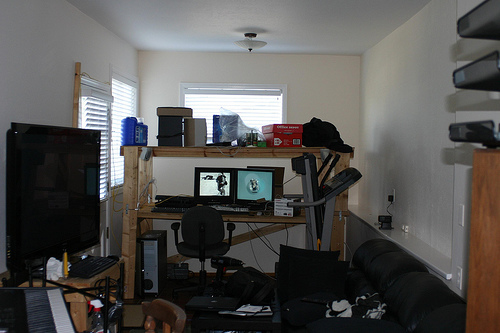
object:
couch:
[272, 236, 466, 332]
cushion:
[416, 303, 470, 333]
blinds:
[81, 96, 109, 200]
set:
[85, 87, 108, 195]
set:
[109, 82, 136, 187]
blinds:
[111, 77, 137, 188]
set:
[187, 95, 279, 139]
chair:
[169, 206, 237, 299]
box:
[261, 123, 304, 148]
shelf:
[119, 145, 352, 157]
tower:
[135, 229, 170, 300]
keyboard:
[69, 256, 117, 279]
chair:
[134, 297, 188, 333]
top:
[138, 297, 190, 333]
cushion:
[368, 251, 431, 294]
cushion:
[381, 271, 463, 332]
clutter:
[154, 105, 354, 154]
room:
[0, 2, 500, 333]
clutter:
[138, 229, 170, 298]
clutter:
[184, 265, 279, 322]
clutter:
[34, 277, 128, 333]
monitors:
[232, 170, 279, 207]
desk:
[117, 199, 353, 302]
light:
[235, 32, 268, 52]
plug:
[388, 195, 393, 202]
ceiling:
[69, 0, 429, 57]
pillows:
[286, 254, 349, 301]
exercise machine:
[287, 151, 364, 254]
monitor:
[194, 167, 238, 200]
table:
[8, 253, 126, 332]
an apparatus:
[377, 195, 395, 231]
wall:
[361, 10, 479, 289]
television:
[2, 121, 104, 274]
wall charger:
[377, 194, 396, 230]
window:
[79, 74, 110, 200]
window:
[183, 85, 284, 141]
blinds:
[185, 92, 283, 143]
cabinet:
[117, 144, 353, 300]